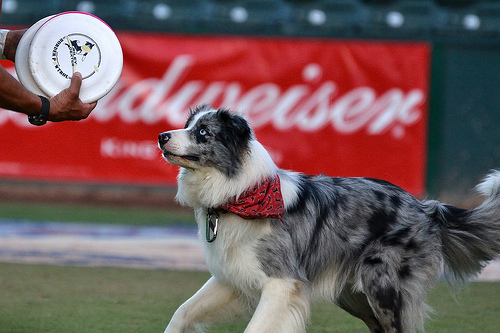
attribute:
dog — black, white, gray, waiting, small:
[154, 103, 496, 327]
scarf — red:
[210, 175, 297, 222]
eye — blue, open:
[197, 127, 208, 135]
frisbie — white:
[13, 12, 124, 101]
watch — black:
[30, 91, 51, 126]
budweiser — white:
[10, 73, 416, 139]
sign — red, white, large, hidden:
[5, 31, 426, 187]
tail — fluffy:
[426, 167, 499, 276]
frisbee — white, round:
[30, 18, 123, 98]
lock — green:
[201, 208, 220, 242]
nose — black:
[155, 131, 174, 144]